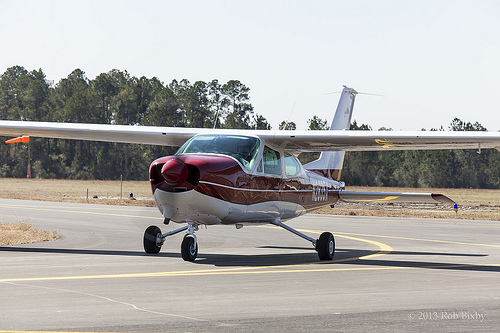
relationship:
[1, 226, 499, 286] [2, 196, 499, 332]
stripe on pavement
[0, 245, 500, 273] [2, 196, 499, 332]
shadow on pavement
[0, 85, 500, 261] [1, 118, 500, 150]
airplane has wings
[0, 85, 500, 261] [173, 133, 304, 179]
airplane has windows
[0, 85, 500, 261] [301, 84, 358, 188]
airplane has tail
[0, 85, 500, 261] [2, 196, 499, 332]
airplane on pavement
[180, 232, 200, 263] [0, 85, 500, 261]
front wheel of airplane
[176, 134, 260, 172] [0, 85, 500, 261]
cockpit window of airplane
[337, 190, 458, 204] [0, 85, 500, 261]
rear wing of airplane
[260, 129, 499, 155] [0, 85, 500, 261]
wing of airplane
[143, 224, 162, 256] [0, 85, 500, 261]
right wheel of airplane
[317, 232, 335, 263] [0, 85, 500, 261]
left wheel of airplane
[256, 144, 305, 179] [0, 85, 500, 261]
side windows of airplane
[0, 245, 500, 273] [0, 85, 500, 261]
shadow of airplane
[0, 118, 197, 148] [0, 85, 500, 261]
wings of airplane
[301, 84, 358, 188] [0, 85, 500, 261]
tail of airplane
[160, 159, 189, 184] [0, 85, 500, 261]
nose of airplane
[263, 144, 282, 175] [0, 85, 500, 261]
window of airplane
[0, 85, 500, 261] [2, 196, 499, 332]
airplane in pavement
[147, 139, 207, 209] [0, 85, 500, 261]
propeller on airplane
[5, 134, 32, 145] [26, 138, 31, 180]
windsock on pole